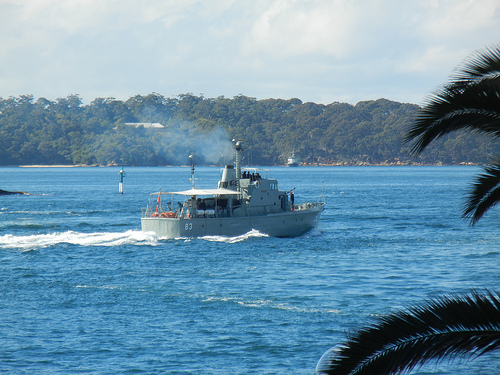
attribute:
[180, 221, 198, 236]
83 — white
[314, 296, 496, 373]
tree — green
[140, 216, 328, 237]
boat — grey, white, moving, small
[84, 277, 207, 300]
water — white, blue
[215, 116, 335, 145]
trees — distant, row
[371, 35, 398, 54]
sky — blue, cloudy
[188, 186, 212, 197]
overhang — white